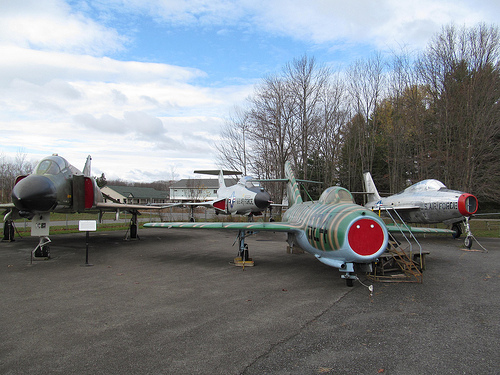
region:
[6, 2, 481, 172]
The sky is blue.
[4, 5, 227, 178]
The clouds are white.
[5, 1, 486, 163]
The sky is cloudy.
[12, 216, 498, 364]
The ground is concrete.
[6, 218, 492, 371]
The ground is grey.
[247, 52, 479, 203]
The trees are bare.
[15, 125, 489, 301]
Four planes are parked.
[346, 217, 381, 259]
The front of the plane is red.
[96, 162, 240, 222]
Buildings in the background.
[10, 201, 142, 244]
The grass is green.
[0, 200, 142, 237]
the grass is green.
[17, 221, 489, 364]
the ground is grey.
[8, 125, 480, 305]
Planes parked on the street.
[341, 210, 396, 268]
The head of the plane is red.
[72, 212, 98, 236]
The sign is white.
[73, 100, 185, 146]
a cloud in the sky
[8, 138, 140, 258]
the first air plane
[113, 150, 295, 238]
the second air plane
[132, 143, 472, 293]
the third air plane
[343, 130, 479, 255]
the fourth air plane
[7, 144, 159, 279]
the left air plane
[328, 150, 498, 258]
the right air plane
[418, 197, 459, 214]
US AIR FORCE in black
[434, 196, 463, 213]
the word FORCE in black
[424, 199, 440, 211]
the word Air in black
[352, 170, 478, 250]
silver plane with red circle on the nose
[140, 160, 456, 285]
green plane with yellow stripes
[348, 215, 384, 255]
red circle on the nose of the green striped plane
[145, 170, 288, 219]
silver plane with a black nose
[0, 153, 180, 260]
dark colored plane with a black nose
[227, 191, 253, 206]
star logo and US Air Force on the side of the silver plane with the black nose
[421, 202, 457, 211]
US Air Force written on the front side of the silver plane with the red nose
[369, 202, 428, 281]
stairs to the side of the green striped plane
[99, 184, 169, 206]
tan building with a dark roof in background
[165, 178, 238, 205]
light blue building in background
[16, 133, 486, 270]
The four planes are parked together.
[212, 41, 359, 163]
The trees are barren.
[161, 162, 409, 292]
The plane has green, yellow, and red on it.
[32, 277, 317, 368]
The ground has concrete on it.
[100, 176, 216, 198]
Two buildings are in the distance.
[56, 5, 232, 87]
The sky is blue and cloudy.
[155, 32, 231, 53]
A patch of blue sky.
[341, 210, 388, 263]
The tip of the airplane is red.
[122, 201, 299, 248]
The wing of an airplane.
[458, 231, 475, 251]
The front wheel on an airplane.